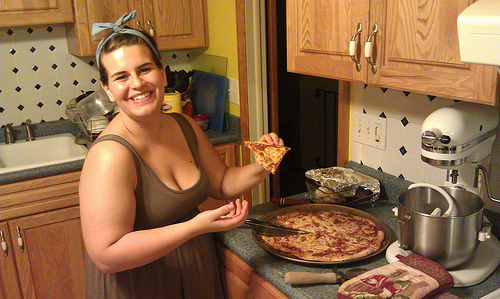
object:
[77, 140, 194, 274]
arm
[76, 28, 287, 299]
woman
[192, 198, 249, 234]
hand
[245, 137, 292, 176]
slice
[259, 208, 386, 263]
pizza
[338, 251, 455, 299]
mitt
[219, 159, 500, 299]
counter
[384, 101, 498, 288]
mixer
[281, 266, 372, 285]
cutter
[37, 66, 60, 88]
tile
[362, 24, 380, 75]
handle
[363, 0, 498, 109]
cabinet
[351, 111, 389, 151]
outlet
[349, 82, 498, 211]
wall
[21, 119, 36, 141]
fuacet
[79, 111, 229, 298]
dress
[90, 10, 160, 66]
headband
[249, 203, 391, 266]
pan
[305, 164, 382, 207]
foil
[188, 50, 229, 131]
board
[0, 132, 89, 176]
sink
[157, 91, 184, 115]
container